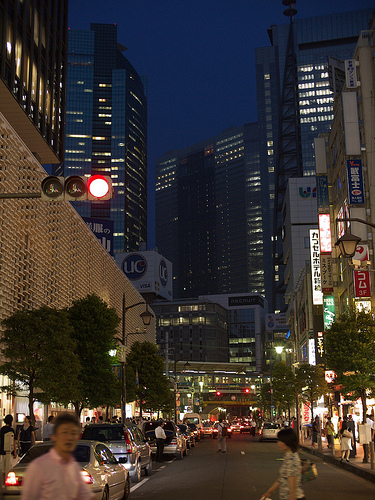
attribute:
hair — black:
[280, 429, 296, 448]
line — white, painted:
[129, 473, 150, 492]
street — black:
[129, 428, 317, 498]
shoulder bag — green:
[297, 460, 318, 484]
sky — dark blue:
[85, 8, 355, 266]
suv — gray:
[84, 422, 156, 484]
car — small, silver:
[6, 440, 130, 498]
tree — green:
[6, 304, 80, 447]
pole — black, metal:
[121, 293, 144, 444]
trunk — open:
[141, 418, 179, 447]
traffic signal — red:
[38, 171, 117, 200]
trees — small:
[9, 300, 179, 434]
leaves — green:
[5, 297, 109, 403]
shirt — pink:
[21, 453, 91, 498]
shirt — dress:
[277, 454, 302, 499]